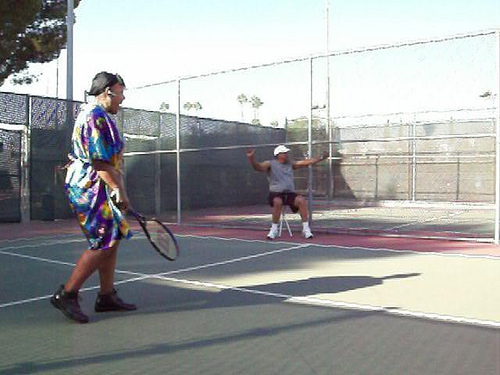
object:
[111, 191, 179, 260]
racket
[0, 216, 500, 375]
court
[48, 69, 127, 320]
player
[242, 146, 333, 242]
spectator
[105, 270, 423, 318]
shadow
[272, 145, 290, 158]
hat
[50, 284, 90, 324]
shoe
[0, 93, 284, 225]
fence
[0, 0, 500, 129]
sky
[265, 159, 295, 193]
tank top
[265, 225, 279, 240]
shoe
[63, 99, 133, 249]
dress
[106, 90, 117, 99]
phone earpiece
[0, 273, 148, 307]
line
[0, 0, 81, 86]
tree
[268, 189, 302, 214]
shorts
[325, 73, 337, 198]
pole